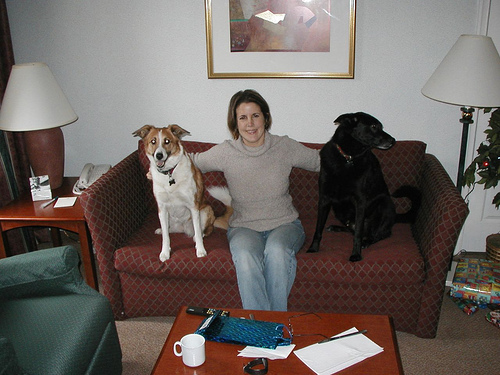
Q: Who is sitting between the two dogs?
A: Dogs owner.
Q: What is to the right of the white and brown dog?
A: End table.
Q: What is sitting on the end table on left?
A: Lamp.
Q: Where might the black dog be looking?
A: At christmas tree.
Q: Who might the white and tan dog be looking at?
A: Photographer.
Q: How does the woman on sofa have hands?
A: On dogs.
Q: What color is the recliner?
A: Dark green.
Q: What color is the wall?
A: White.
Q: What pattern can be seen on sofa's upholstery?
A: Diamond shapes.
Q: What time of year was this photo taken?
A: At christmas.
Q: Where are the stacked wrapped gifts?
A: On the floor.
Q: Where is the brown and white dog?
A: Sitting on the sofa.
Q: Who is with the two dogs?
A: A smiling young woman.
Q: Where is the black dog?
A: On the couch.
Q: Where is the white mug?
A: On the coffee table.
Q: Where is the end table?
A: To the left of the couch.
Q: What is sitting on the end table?
A: A lamp.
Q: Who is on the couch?
A: A woman with two dogs.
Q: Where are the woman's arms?
A: Around dogs.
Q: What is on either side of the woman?
A: A dog.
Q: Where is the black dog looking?
A: To the right.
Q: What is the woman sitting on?
A: A couch.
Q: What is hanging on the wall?
A: One framed picture.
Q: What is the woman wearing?
A: A tan sweater and blue jeans.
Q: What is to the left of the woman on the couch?
A: A brown and white dog.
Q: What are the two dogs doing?
A: Sitting on the couch.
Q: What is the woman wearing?
A: Jeans and a sweater.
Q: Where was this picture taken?
A: In a living room.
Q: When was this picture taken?
A: During the day.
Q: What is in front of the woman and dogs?
A: A coffee table.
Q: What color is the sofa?
A: Red.